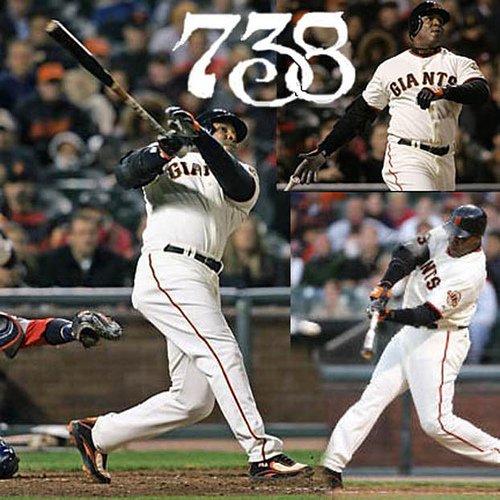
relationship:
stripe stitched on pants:
[436, 331, 496, 458] [321, 269, 494, 484]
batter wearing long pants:
[67, 107, 316, 481] [90, 240, 285, 462]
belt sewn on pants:
[164, 245, 222, 273] [88, 250, 285, 463]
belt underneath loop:
[164, 247, 223, 272] [177, 237, 198, 262]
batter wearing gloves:
[67, 103, 305, 483] [153, 108, 202, 155]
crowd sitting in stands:
[1, 2, 498, 309] [1, 182, 498, 439]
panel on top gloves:
[370, 285, 393, 300] [364, 287, 393, 324]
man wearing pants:
[67, 106, 314, 483] [88, 250, 285, 463]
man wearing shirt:
[67, 106, 314, 483] [137, 149, 260, 263]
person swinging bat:
[315, 204, 500, 492] [35, 24, 184, 140]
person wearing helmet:
[346, 200, 485, 460] [433, 205, 490, 242]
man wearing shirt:
[67, 106, 314, 483] [112, 136, 263, 259]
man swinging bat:
[64, 107, 309, 485] [45, 18, 178, 145]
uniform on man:
[92, 146, 284, 460] [73, 106, 276, 409]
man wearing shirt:
[338, 39, 488, 193] [362, 50, 490, 143]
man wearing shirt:
[292, 0, 489, 191] [320, 82, 490, 174]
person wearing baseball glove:
[0, 308, 73, 478] [70, 308, 120, 347]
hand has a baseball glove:
[69, 310, 119, 349] [73, 310, 123, 349]